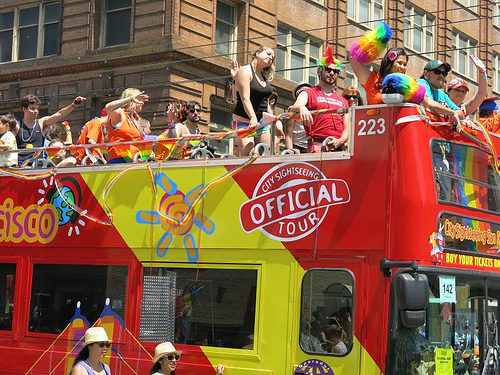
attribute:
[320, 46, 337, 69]
mohawk — rainbow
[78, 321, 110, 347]
fedora — brown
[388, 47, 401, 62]
flower — pink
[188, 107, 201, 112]
sunglasses — dark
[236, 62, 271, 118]
tank top — black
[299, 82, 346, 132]
t shirt — red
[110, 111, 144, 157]
tank top — orange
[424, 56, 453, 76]
hat — green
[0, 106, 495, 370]
bus — red, large